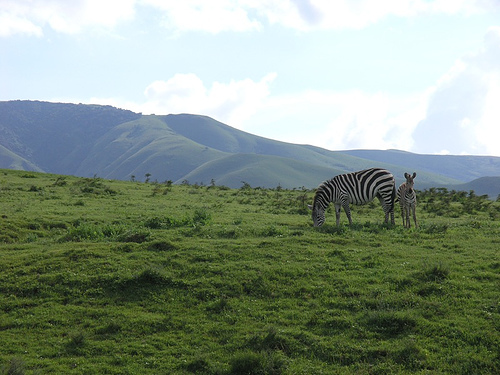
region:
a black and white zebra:
[309, 167, 397, 232]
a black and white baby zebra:
[395, 166, 418, 224]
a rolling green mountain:
[2, 98, 498, 195]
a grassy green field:
[3, 170, 498, 371]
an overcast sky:
[2, 3, 498, 158]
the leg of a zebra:
[332, 197, 342, 224]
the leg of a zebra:
[343, 198, 352, 221]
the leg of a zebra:
[377, 196, 389, 228]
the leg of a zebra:
[383, 196, 395, 227]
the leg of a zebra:
[406, 203, 411, 226]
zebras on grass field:
[47, 54, 478, 374]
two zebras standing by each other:
[242, 152, 437, 263]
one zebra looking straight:
[398, 165, 430, 229]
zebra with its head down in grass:
[278, 154, 402, 235]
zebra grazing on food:
[305, 174, 409, 212]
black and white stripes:
[315, 121, 463, 238]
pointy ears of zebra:
[404, 167, 418, 188]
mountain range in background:
[5, 78, 333, 248]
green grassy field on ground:
[35, 172, 279, 367]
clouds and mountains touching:
[2, 21, 326, 166]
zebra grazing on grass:
[307, 167, 399, 238]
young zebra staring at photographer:
[390, 165, 423, 232]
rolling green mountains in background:
[72, 103, 299, 188]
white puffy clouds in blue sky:
[110, 17, 462, 132]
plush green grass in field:
[97, 259, 322, 356]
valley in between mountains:
[28, 139, 110, 189]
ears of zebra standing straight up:
[402, 170, 417, 180]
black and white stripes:
[335, 173, 375, 195]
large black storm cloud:
[410, 65, 485, 158]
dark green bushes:
[430, 182, 481, 212]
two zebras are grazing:
[299, 142, 424, 234]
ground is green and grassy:
[10, 180, 465, 356]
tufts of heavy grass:
[7, 163, 288, 335]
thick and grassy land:
[8, 181, 215, 344]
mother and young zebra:
[310, 162, 427, 242]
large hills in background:
[1, 85, 408, 185]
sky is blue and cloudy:
[244, 0, 434, 135]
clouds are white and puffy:
[180, 70, 465, 151]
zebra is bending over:
[314, 166, 393, 254]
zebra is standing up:
[390, 170, 425, 231]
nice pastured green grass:
[97, 200, 238, 334]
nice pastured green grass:
[130, 237, 225, 345]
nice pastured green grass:
[114, 212, 188, 297]